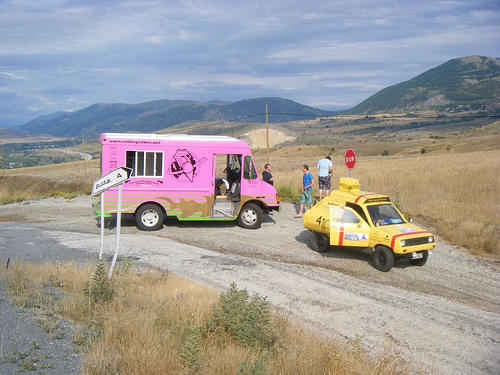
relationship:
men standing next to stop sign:
[263, 157, 341, 200] [345, 149, 356, 167]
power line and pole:
[217, 109, 420, 126] [260, 99, 273, 167]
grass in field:
[355, 158, 496, 221] [240, 145, 498, 247]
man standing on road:
[302, 163, 312, 207] [43, 177, 498, 370]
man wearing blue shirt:
[302, 163, 312, 207] [300, 175, 316, 187]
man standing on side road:
[322, 158, 337, 193] [43, 177, 498, 370]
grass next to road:
[355, 158, 496, 221] [43, 177, 498, 370]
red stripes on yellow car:
[334, 224, 346, 245] [305, 184, 437, 270]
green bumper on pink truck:
[90, 202, 114, 218] [99, 136, 284, 226]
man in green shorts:
[302, 163, 312, 207] [300, 190, 312, 204]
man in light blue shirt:
[322, 158, 337, 193] [318, 158, 332, 173]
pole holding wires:
[260, 99, 273, 167] [201, 99, 478, 135]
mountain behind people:
[348, 57, 499, 116] [263, 157, 341, 200]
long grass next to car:
[355, 158, 496, 221] [305, 184, 437, 270]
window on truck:
[129, 153, 165, 176] [99, 136, 284, 226]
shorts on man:
[315, 175, 338, 188] [322, 158, 337, 193]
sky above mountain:
[0, 3, 494, 87] [348, 57, 499, 116]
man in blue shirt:
[294, 163, 316, 218] [300, 175, 316, 187]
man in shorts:
[322, 158, 337, 193] [315, 175, 338, 188]